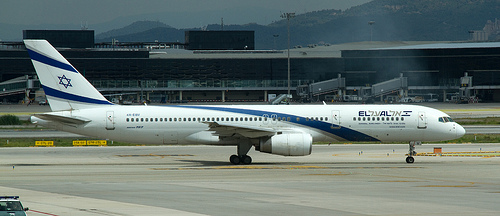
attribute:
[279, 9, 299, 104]
pole is tall — light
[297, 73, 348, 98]
tunnel is gray — long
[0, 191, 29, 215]
vehicle is on runway — support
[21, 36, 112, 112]
plane has tail — blue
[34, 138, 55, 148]
sign is yellow — runway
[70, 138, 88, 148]
sign is small — runway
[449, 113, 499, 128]
grass is green — small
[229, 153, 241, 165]
plane has wheel — back, landing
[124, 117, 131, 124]
plane has window — long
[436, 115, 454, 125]
plane has windshield — in front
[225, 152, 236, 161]
plane has wheel — under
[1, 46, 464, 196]
airplane — white and blue